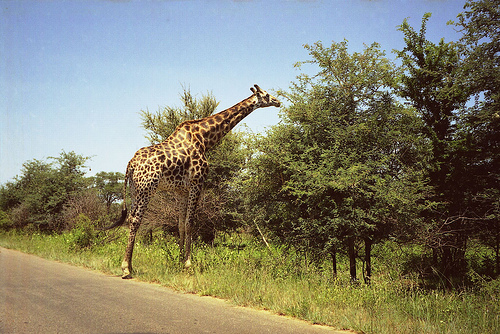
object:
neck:
[205, 93, 259, 141]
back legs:
[119, 188, 152, 270]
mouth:
[270, 99, 281, 107]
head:
[249, 84, 282, 109]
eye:
[264, 93, 273, 97]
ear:
[255, 91, 265, 105]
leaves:
[302, 118, 316, 139]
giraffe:
[118, 84, 282, 281]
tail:
[101, 164, 134, 231]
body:
[103, 94, 256, 281]